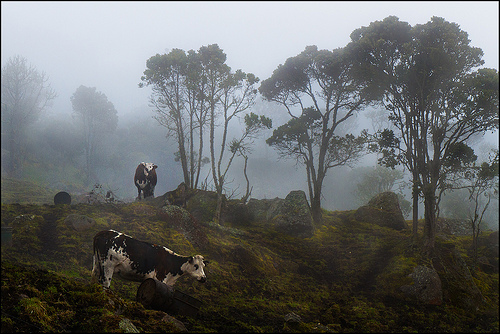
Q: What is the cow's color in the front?
A: Black and white.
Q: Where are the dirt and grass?
A: On the hill.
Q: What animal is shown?
A: Cow.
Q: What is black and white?
A: Cows.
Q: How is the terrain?
A: Rocky.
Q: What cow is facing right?
A: Foreground cow.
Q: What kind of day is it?
A: Foggy.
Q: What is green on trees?
A: Leaves.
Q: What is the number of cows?
A: Two.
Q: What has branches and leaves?
A: Trees.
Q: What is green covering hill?
A: Grass.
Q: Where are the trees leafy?
A: On top.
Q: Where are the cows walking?
A: Down a hill.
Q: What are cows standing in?
A: Rain.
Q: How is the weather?
A: Foggy.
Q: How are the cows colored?
A: Black and white.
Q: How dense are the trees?
A: Sparse.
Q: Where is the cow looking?
A: Down hill.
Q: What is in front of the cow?
A: Fallen tree.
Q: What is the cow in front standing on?
A: A hill.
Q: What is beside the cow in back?
A: A group of trees.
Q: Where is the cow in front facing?
A: Downhill.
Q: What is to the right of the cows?
A: Large moss covered rocks.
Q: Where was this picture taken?
A: In a foggy rocky wooded area.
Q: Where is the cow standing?
A: On uneven ground.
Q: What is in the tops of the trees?
A: Leaves.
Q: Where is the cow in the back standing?
A: On top of a hill.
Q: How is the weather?
A: Foggy.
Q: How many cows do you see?
A: Two.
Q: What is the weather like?
A: Foggy.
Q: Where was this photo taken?
A: Outside in the pasture.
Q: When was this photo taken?
A: During the day.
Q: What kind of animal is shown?
A: Cows.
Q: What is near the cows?
A: Trees.